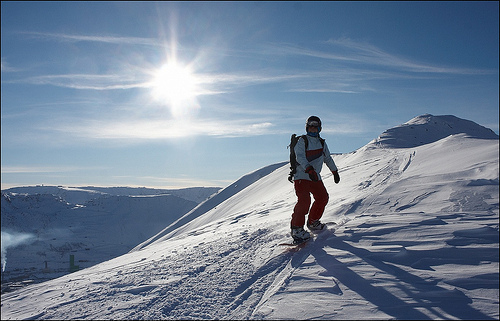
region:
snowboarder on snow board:
[273, 105, 349, 251]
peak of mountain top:
[362, 104, 498, 143]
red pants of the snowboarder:
[284, 173, 333, 230]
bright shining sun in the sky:
[122, 29, 224, 137]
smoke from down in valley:
[1, 222, 45, 282]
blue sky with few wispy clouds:
[7, 7, 492, 119]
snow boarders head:
[302, 109, 329, 137]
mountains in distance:
[6, 179, 226, 222]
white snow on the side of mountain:
[348, 156, 485, 311]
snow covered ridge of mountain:
[121, 158, 285, 246]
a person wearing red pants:
[283, 169, 365, 270]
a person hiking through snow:
[288, 83, 385, 312]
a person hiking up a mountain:
[282, 102, 361, 291]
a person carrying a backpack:
[279, 128, 321, 192]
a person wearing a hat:
[293, 103, 320, 150]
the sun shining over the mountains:
[118, 44, 211, 129]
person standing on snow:
[258, 108, 367, 269]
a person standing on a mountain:
[273, 105, 351, 245]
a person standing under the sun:
[268, 117, 385, 252]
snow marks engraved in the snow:
[194, 242, 272, 307]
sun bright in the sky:
[140, 44, 223, 125]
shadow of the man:
[321, 245, 442, 308]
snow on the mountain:
[152, 248, 263, 309]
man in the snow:
[287, 103, 335, 245]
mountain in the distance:
[5, 178, 91, 222]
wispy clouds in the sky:
[307, 45, 440, 73]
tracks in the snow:
[144, 268, 234, 313]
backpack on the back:
[281, 132, 306, 183]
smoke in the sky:
[2, 232, 34, 247]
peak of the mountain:
[379, 104, 476, 147]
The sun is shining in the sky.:
[126, 47, 271, 139]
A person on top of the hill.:
[283, 94, 333, 251]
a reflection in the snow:
[281, 225, 464, 305]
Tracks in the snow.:
[351, 135, 438, 200]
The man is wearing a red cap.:
[303, 113, 330, 132]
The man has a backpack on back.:
[279, 125, 307, 171]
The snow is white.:
[67, 230, 394, 316]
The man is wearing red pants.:
[297, 174, 349, 224]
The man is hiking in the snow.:
[281, 97, 359, 229]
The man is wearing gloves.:
[308, 163, 352, 187]